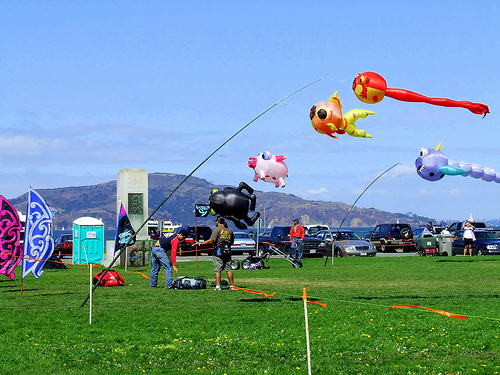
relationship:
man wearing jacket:
[154, 227, 196, 272] [160, 232, 174, 250]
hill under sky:
[12, 172, 412, 236] [80, 23, 191, 98]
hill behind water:
[12, 172, 412, 236] [347, 220, 367, 230]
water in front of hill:
[347, 220, 367, 230] [12, 172, 412, 236]